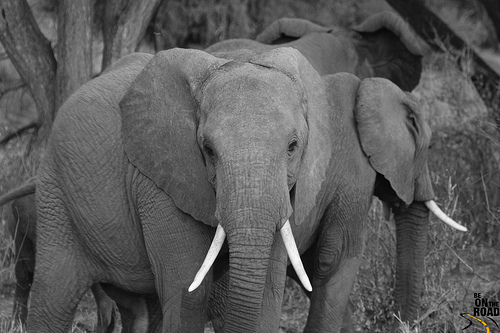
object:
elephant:
[299, 71, 467, 333]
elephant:
[24, 45, 333, 333]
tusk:
[424, 199, 467, 232]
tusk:
[379, 200, 390, 222]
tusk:
[279, 219, 313, 292]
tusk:
[188, 222, 227, 292]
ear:
[119, 48, 229, 228]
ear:
[248, 46, 333, 225]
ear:
[355, 77, 415, 208]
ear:
[349, 10, 432, 93]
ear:
[254, 17, 332, 44]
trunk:
[218, 224, 277, 333]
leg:
[24, 182, 93, 332]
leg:
[101, 283, 149, 332]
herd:
[117, 44, 333, 333]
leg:
[132, 174, 213, 333]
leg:
[300, 174, 379, 332]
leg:
[257, 230, 289, 332]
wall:
[224, 83, 272, 130]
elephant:
[203, 10, 423, 94]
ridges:
[240, 230, 262, 313]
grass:
[0, 6, 500, 333]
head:
[256, 11, 432, 93]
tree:
[0, 0, 160, 160]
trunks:
[3, 0, 158, 128]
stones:
[10, 197, 36, 300]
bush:
[351, 116, 498, 333]